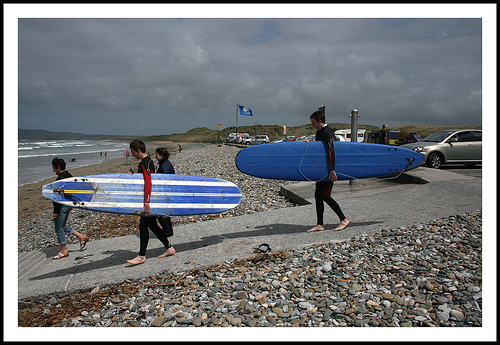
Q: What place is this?
A: It is a walkway.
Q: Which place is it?
A: It is a walkway.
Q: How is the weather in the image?
A: It is cloudy.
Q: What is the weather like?
A: It is cloudy.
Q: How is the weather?
A: It is cloudy.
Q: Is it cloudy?
A: Yes, it is cloudy.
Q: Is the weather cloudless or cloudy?
A: It is cloudy.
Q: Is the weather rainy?
A: No, it is cloudy.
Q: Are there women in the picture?
A: Yes, there is a woman.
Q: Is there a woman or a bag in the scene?
A: Yes, there is a woman.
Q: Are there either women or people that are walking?
A: Yes, the woman is walking.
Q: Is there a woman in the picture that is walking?
A: Yes, there is a woman that is walking.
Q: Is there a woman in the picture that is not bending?
A: Yes, there is a woman that is walking.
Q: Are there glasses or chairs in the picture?
A: No, there are no glasses or chairs.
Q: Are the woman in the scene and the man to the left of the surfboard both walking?
A: Yes, both the woman and the man are walking.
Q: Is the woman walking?
A: Yes, the woman is walking.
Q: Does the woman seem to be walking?
A: Yes, the woman is walking.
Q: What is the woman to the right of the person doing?
A: The woman is walking.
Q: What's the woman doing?
A: The woman is walking.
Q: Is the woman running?
A: No, the woman is walking.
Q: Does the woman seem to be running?
A: No, the woman is walking.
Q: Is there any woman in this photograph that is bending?
A: No, there is a woman but she is walking.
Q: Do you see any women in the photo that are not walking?
A: No, there is a woman but she is walking.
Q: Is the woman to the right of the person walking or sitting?
A: The woman is walking.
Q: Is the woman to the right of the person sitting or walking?
A: The woman is walking.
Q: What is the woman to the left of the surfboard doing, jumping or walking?
A: The woman is walking.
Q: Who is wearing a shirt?
A: The woman is wearing a shirt.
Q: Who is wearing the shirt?
A: The woman is wearing a shirt.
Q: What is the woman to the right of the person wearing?
A: The woman is wearing a shirt.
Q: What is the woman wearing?
A: The woman is wearing a shirt.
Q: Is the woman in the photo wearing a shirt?
A: Yes, the woman is wearing a shirt.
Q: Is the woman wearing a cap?
A: No, the woman is wearing a shirt.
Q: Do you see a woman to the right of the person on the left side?
A: Yes, there is a woman to the right of the person.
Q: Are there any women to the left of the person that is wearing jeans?
A: No, the woman is to the right of the person.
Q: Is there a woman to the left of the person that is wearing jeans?
A: No, the woman is to the right of the person.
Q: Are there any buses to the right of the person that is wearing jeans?
A: No, there is a woman to the right of the person.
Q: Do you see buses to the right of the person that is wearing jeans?
A: No, there is a woman to the right of the person.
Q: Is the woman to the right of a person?
A: Yes, the woman is to the right of a person.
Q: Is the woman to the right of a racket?
A: No, the woman is to the right of a person.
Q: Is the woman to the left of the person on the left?
A: No, the woman is to the right of the person.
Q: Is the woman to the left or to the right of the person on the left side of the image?
A: The woman is to the right of the person.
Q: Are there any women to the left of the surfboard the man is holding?
A: Yes, there is a woman to the left of the surfboard.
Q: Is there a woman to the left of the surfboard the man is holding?
A: Yes, there is a woman to the left of the surfboard.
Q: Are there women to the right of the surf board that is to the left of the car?
A: No, the woman is to the left of the surfboard.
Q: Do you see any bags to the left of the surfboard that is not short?
A: No, there is a woman to the left of the surfboard.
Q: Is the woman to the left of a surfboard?
A: Yes, the woman is to the left of a surfboard.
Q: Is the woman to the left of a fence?
A: No, the woman is to the left of a surfboard.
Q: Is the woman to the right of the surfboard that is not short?
A: No, the woman is to the left of the surfboard.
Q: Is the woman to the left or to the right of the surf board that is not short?
A: The woman is to the left of the surfboard.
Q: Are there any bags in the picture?
A: No, there are no bags.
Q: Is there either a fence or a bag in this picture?
A: No, there are no bags or fences.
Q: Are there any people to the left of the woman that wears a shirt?
A: Yes, there is a person to the left of the woman.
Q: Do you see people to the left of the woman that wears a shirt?
A: Yes, there is a person to the left of the woman.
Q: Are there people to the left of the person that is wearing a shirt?
A: Yes, there is a person to the left of the woman.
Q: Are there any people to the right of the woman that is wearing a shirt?
A: No, the person is to the left of the woman.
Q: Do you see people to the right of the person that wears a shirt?
A: No, the person is to the left of the woman.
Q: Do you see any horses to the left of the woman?
A: No, there is a person to the left of the woman.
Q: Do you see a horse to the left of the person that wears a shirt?
A: No, there is a person to the left of the woman.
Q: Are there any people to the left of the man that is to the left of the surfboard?
A: Yes, there is a person to the left of the man.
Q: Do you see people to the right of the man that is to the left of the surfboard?
A: No, the person is to the left of the man.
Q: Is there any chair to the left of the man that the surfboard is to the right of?
A: No, there is a person to the left of the man.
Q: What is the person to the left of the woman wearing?
A: The person is wearing jeans.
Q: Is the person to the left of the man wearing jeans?
A: Yes, the person is wearing jeans.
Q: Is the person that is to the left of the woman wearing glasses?
A: No, the person is wearing jeans.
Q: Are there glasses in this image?
A: No, there are no glasses.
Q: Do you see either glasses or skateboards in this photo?
A: No, there are no glasses or skateboards.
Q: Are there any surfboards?
A: Yes, there is a surfboard.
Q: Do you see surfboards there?
A: Yes, there is a surfboard.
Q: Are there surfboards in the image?
A: Yes, there is a surfboard.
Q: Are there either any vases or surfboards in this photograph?
A: Yes, there is a surfboard.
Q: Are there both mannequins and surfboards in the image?
A: No, there is a surfboard but no mannequins.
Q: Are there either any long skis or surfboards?
A: Yes, there is a long surfboard.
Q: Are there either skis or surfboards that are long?
A: Yes, the surfboard is long.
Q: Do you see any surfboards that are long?
A: Yes, there is a long surfboard.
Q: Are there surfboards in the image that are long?
A: Yes, there is a surfboard that is long.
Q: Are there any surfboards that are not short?
A: Yes, there is a long surfboard.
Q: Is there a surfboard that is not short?
A: Yes, there is a long surfboard.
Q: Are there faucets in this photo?
A: No, there are no faucets.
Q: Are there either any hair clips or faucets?
A: No, there are no faucets or hair clips.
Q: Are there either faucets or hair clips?
A: No, there are no faucets or hair clips.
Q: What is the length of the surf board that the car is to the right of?
A: The surfboard is long.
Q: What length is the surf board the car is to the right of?
A: The surfboard is long.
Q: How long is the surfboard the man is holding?
A: The surf board is long.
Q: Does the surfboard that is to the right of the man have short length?
A: No, the surfboard is long.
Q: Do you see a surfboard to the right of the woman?
A: Yes, there is a surfboard to the right of the woman.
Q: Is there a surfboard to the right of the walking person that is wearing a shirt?
A: Yes, there is a surfboard to the right of the woman.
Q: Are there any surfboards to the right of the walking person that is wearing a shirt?
A: Yes, there is a surfboard to the right of the woman.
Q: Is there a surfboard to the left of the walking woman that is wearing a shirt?
A: No, the surfboard is to the right of the woman.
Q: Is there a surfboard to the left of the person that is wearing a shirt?
A: No, the surfboard is to the right of the woman.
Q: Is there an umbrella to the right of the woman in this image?
A: No, there is a surfboard to the right of the woman.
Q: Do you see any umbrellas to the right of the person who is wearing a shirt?
A: No, there is a surfboard to the right of the woman.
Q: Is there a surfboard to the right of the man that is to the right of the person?
A: Yes, there is a surfboard to the right of the man.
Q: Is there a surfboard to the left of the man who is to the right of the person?
A: No, the surfboard is to the right of the man.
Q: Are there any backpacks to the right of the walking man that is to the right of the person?
A: No, there is a surfboard to the right of the man.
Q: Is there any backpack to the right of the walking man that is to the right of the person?
A: No, there is a surfboard to the right of the man.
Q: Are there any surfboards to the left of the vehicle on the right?
A: Yes, there is a surfboard to the left of the car.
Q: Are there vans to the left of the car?
A: No, there is a surfboard to the left of the car.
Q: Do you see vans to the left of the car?
A: No, there is a surfboard to the left of the car.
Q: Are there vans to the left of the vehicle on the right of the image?
A: No, there is a surfboard to the left of the car.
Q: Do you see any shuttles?
A: No, there are no shuttles.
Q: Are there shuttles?
A: No, there are no shuttles.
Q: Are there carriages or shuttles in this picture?
A: No, there are no shuttles or carriages.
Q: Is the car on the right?
A: Yes, the car is on the right of the image.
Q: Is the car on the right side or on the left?
A: The car is on the right of the image.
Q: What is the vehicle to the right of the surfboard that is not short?
A: The vehicle is a car.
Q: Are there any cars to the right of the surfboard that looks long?
A: Yes, there is a car to the right of the surfboard.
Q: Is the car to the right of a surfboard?
A: Yes, the car is to the right of a surfboard.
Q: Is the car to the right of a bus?
A: No, the car is to the right of a surfboard.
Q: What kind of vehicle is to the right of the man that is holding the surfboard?
A: The vehicle is a car.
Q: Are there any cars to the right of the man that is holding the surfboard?
A: Yes, there is a car to the right of the man.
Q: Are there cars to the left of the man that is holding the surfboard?
A: No, the car is to the right of the man.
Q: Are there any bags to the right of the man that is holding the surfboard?
A: No, there is a car to the right of the man.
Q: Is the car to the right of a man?
A: Yes, the car is to the right of a man.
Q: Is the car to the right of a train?
A: No, the car is to the right of a man.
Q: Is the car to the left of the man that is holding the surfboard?
A: No, the car is to the right of the man.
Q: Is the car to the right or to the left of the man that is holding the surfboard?
A: The car is to the right of the man.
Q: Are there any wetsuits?
A: Yes, there is a wetsuit.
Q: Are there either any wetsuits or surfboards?
A: Yes, there is a wetsuit.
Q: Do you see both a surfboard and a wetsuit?
A: Yes, there are both a wetsuit and a surfboard.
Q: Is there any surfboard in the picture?
A: Yes, there is a surfboard.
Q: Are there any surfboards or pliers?
A: Yes, there is a surfboard.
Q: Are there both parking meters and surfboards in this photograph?
A: No, there is a surfboard but no parking meters.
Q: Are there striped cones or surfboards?
A: Yes, there is a striped surfboard.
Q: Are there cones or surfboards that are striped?
A: Yes, the surfboard is striped.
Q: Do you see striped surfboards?
A: Yes, there is a striped surfboard.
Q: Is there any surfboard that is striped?
A: Yes, there is a surfboard that is striped.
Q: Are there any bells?
A: No, there are no bells.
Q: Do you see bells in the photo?
A: No, there are no bells.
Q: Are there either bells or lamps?
A: No, there are no bells or lamps.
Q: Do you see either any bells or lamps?
A: No, there are no bells or lamps.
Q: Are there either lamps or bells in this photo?
A: No, there are no bells or lamps.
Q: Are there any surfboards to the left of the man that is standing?
A: Yes, there is a surfboard to the left of the man.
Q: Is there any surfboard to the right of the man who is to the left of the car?
A: No, the surfboard is to the left of the man.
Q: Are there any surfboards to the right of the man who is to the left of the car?
A: No, the surfboard is to the left of the man.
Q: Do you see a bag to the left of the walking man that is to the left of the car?
A: No, there is a surfboard to the left of the man.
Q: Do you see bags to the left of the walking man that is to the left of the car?
A: No, there is a surfboard to the left of the man.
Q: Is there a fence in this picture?
A: No, there are no fences.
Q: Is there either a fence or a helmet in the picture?
A: No, there are no fences or helmets.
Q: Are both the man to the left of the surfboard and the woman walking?
A: Yes, both the man and the woman are walking.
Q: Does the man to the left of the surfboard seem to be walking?
A: Yes, the man is walking.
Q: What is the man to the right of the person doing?
A: The man is walking.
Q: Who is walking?
A: The man is walking.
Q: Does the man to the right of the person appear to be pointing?
A: No, the man is walking.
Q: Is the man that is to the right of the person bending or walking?
A: The man is walking.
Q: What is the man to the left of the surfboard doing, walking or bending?
A: The man is walking.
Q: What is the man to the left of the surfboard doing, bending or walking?
A: The man is walking.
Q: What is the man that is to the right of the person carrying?
A: The man is carrying a surfboard.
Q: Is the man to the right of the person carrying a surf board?
A: Yes, the man is carrying a surf board.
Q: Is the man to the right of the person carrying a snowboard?
A: No, the man is carrying a surf board.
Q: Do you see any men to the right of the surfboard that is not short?
A: No, the man is to the left of the surfboard.